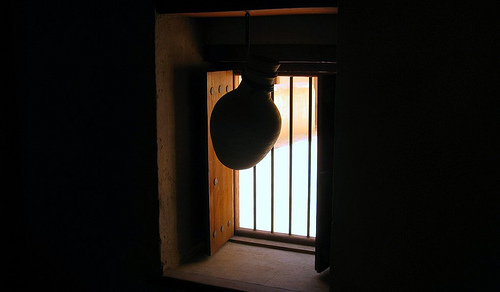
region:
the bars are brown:
[237, 172, 309, 239]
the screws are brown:
[207, 217, 237, 239]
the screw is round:
[210, 171, 221, 189]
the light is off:
[193, 48, 291, 168]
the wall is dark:
[374, 57, 461, 169]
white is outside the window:
[256, 177, 308, 223]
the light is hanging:
[203, 47, 287, 180]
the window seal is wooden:
[227, 247, 303, 280]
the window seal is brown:
[227, 235, 294, 282]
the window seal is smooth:
[231, 241, 296, 278]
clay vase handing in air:
[206, 53, 291, 173]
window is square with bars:
[229, 65, 321, 247]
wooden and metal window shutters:
[193, 58, 336, 274]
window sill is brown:
[154, 5, 344, 290]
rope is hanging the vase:
[240, 5, 282, 102]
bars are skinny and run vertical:
[233, 68, 320, 241]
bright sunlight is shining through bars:
[231, 70, 317, 245]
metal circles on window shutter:
[207, 78, 232, 238]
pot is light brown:
[208, 55, 283, 174]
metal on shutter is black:
[206, 78, 233, 240]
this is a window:
[224, 70, 319, 254]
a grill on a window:
[305, 78, 316, 248]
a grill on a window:
[280, 73, 302, 238]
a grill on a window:
[258, 85, 282, 234]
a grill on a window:
[245, 169, 267, 231]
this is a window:
[200, 59, 248, 259]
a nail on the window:
[202, 83, 218, 98]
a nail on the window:
[207, 172, 224, 194]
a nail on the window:
[212, 217, 220, 252]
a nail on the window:
[217, 215, 234, 237]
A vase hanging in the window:
[202, 50, 292, 175]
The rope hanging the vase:
[230, 7, 290, 92]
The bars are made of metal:
[277, 92, 322, 246]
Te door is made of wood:
[300, 70, 335, 275]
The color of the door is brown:
[194, 59, 251, 259]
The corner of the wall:
[125, 21, 189, 268]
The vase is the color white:
[199, 45, 295, 160]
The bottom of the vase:
[204, 120, 281, 172]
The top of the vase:
[218, 48, 291, 127]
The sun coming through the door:
[220, 78, 313, 243]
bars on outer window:
[225, 67, 322, 244]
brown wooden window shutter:
[195, 67, 238, 256]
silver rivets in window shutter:
[209, 218, 234, 245]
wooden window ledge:
[162, 229, 373, 290]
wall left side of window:
[145, 10, 220, 274]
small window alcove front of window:
[146, 3, 365, 290]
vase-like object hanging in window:
[210, 10, 287, 177]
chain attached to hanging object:
[237, 4, 263, 62]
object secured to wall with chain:
[207, 6, 287, 179]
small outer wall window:
[189, 43, 341, 277]